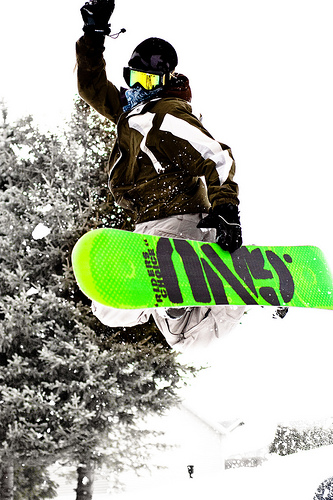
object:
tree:
[0, 83, 209, 500]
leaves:
[70, 391, 82, 410]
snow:
[0, 0, 333, 499]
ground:
[52, 332, 331, 498]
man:
[74, 0, 292, 346]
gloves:
[196, 204, 241, 253]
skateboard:
[70, 224, 333, 312]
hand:
[198, 203, 242, 253]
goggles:
[124, 70, 168, 93]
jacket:
[75, 31, 239, 222]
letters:
[133, 226, 299, 309]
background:
[0, 0, 330, 499]